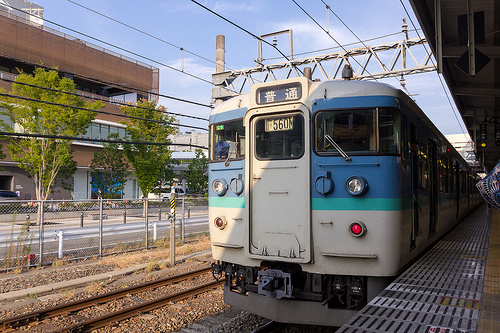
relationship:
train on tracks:
[212, 81, 489, 317] [24, 255, 281, 332]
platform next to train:
[382, 196, 500, 326] [212, 81, 489, 317]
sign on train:
[259, 88, 301, 102] [212, 81, 489, 317]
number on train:
[265, 118, 298, 130] [212, 81, 489, 317]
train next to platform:
[212, 81, 489, 317] [382, 196, 500, 326]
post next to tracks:
[166, 180, 179, 266] [24, 255, 281, 332]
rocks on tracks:
[145, 304, 189, 332] [24, 255, 281, 332]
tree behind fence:
[7, 73, 94, 255] [0, 199, 212, 245]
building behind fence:
[3, 22, 162, 205] [0, 199, 212, 245]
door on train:
[251, 113, 309, 261] [212, 81, 489, 317]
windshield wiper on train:
[321, 134, 347, 156] [212, 81, 489, 317]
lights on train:
[212, 176, 228, 192] [212, 81, 489, 317]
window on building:
[93, 173, 127, 196] [3, 22, 162, 205]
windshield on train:
[316, 110, 398, 149] [212, 81, 489, 317]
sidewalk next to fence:
[23, 217, 155, 250] [0, 199, 212, 245]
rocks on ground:
[145, 304, 189, 332] [2, 209, 312, 332]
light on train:
[351, 221, 364, 235] [212, 81, 489, 317]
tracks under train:
[24, 255, 281, 332] [212, 81, 489, 317]